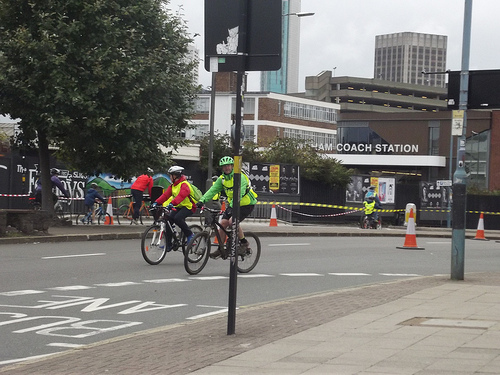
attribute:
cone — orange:
[396, 209, 425, 253]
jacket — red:
[145, 177, 195, 209]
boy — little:
[156, 162, 206, 247]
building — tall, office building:
[365, 20, 418, 117]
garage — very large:
[327, 70, 448, 112]